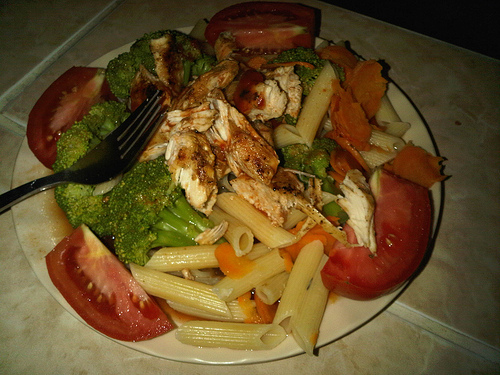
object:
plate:
[7, 25, 442, 371]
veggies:
[39, 62, 202, 329]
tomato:
[316, 175, 432, 303]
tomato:
[44, 227, 176, 349]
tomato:
[27, 65, 107, 167]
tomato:
[207, 0, 322, 51]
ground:
[311, 239, 337, 268]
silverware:
[0, 88, 169, 218]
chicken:
[137, 33, 317, 213]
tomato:
[25, 0, 449, 342]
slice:
[44, 221, 174, 343]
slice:
[321, 166, 433, 300]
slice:
[202, 0, 322, 57]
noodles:
[135, 227, 348, 360]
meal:
[26, 2, 446, 373]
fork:
[0, 90, 172, 212]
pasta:
[123, 184, 363, 357]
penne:
[280, 239, 331, 319]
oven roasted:
[136, 50, 306, 220]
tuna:
[237, 67, 331, 177]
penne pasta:
[81, 64, 419, 354]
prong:
[123, 87, 171, 155]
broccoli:
[57, 28, 361, 270]